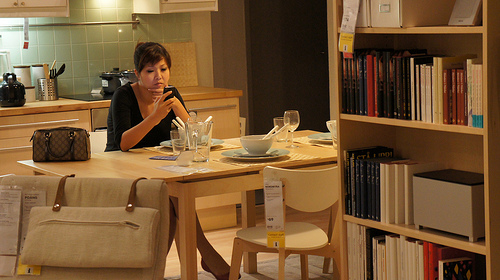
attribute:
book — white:
[470, 64, 478, 131]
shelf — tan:
[343, 107, 485, 132]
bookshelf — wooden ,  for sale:
[327, 0, 499, 278]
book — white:
[382, 236, 399, 278]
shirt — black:
[102, 82, 191, 154]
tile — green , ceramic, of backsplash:
[83, 19, 110, 50]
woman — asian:
[101, 41, 243, 278]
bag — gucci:
[30, 127, 91, 164]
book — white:
[425, 66, 432, 121]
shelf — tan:
[333, 0, 498, 279]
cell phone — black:
[160, 83, 178, 113]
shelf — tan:
[339, 110, 486, 136]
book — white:
[467, 58, 474, 126]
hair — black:
[129, 38, 172, 69]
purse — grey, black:
[23, 126, 110, 169]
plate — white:
[219, 147, 289, 161]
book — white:
[409, 57, 416, 119]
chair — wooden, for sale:
[225, 165, 339, 278]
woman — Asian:
[126, 47, 191, 140]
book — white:
[381, 159, 383, 222]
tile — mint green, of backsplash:
[94, 28, 105, 43]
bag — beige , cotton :
[20, 175, 160, 270]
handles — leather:
[43, 175, 149, 203]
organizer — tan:
[21, 174, 158, 268]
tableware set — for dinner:
[140, 109, 335, 167]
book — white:
[403, 45, 446, 134]